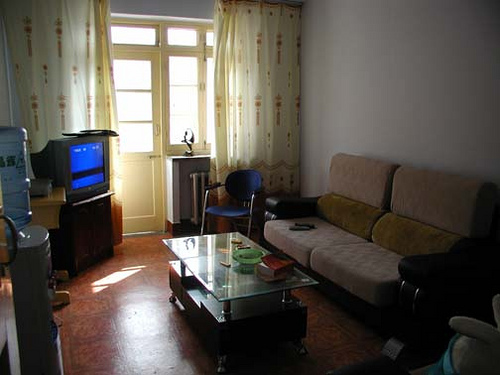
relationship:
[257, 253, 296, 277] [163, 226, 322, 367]
book on table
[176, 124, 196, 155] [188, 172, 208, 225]
trophy on radiator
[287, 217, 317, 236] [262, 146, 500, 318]
controls on love seat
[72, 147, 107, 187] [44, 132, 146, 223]
color on television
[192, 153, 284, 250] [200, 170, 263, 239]
chair with chair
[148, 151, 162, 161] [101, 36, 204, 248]
bracket on door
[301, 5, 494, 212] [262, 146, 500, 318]
walls behind love seat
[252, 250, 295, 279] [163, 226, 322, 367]
book on table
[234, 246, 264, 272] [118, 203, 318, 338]
bowl on table